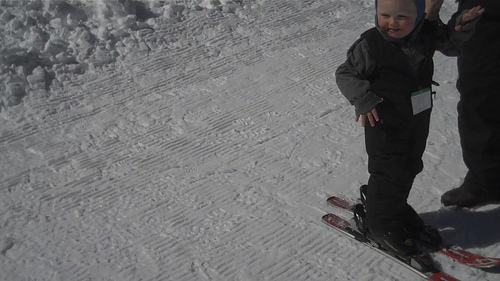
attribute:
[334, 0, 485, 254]
toddler — skiing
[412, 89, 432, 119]
tag — identification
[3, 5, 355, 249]
snow — beautiful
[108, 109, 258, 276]
snow — smoothed over